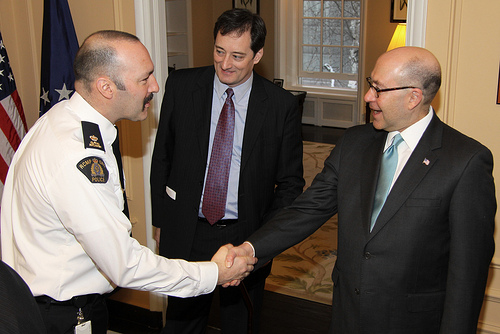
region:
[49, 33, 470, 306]
Two men shaking hands.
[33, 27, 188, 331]
A man wearing a uniform.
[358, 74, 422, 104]
Glasses on a face.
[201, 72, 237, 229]
A tie around a man's neck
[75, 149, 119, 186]
A patch on a shirt.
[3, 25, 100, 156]
Flags in the background.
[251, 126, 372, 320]
A rug on the floor.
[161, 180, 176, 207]
Pamphlet in a pocket.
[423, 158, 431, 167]
An american flag pin.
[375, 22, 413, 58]
A lamp in the background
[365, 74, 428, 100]
Glasses on his face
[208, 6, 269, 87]
Man has smile on his face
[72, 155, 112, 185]
Police badge on his shoulder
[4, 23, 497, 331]
Two men shaking hands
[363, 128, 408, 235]
Wearing a blue tie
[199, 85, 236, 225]
Wearing a red tie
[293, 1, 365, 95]
Open window in the background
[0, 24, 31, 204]
American flag in the background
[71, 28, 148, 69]
Typical male pattern baldness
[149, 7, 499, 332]
Two men wearing suits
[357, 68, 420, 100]
pair of black glasses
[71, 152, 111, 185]
badge on a white shirt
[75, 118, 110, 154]
badge on a white shirt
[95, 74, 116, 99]
ear on a person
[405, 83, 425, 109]
ear on a person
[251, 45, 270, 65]
ear on a person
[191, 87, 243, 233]
tie on a person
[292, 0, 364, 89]
window in a building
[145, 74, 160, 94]
nose of a person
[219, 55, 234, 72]
nose of a person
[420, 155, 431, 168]
A red, white and blue flag pin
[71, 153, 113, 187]
A black and gold shoulder patch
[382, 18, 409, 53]
A yellow lamp shade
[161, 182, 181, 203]
A white piece of paper in a jacket pocket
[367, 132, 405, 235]
A light blue tie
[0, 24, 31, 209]
A vertical american flag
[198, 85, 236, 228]
A dark red tie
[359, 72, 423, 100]
A pair of black glasses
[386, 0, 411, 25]
A black picture frame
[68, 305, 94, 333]
A white name tag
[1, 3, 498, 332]
two men shake hands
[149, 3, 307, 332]
man is wearing a purple tie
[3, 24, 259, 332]
man in a white shirt is wearing police insignia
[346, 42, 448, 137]
man is almost bald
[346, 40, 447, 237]
man is wearing a blue silky tie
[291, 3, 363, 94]
a paneled window is partially open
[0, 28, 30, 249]
american flag behind a man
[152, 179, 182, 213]
a piece of paper in a suit jacket pocket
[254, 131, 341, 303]
a patterned rug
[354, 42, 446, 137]
man is smiling with his mouth open